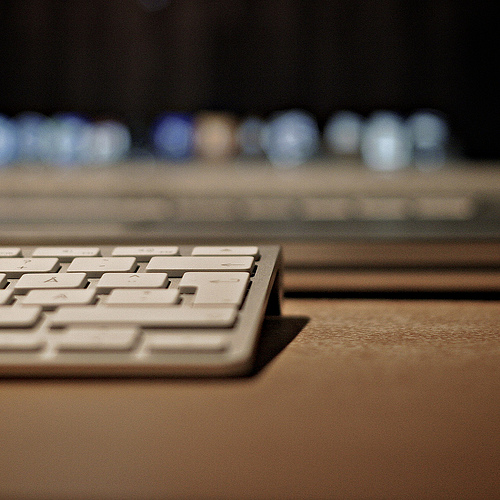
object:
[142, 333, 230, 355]
key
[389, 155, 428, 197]
wall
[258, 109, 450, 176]
blurry objects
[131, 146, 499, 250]
mantel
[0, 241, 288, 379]
key board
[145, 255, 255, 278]
key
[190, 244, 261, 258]
key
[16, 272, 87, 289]
keyboard key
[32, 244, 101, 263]
keyboard key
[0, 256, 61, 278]
key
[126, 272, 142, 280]
symbol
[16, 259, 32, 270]
symbol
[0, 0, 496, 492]
photo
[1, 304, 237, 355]
keys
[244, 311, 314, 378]
shadow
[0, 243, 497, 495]
table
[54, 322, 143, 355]
key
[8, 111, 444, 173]
objects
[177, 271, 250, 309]
key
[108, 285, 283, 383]
brown surface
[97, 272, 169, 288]
computer key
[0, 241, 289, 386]
board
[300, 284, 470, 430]
surface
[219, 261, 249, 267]
arrow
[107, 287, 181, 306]
key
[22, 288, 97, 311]
key